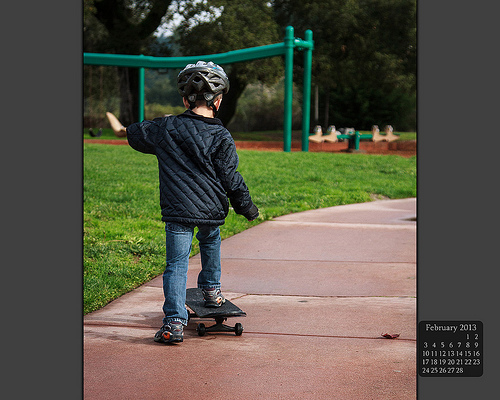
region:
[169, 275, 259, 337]
boy on a skateboard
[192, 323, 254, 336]
wheels on a skateboard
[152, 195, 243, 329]
boy is wearing jeans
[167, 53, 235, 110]
boy is wearing a helmet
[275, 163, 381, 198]
grass by the sidewalk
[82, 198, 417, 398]
sidewalk by the grass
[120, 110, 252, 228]
boy is wearing a black jacket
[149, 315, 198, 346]
boy is wearing a red and black shoe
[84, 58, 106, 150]
swing by the grass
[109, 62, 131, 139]
swing by the grass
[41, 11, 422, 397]
This is in a park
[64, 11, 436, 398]
This is during the daytime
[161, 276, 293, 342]
This kid is on a skateboard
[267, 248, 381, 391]
This ground is pavement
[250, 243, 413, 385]
This pavement is red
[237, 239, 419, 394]
The path is partially wet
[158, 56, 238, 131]
The kids has on a helmet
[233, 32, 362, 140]
These poles are made of metal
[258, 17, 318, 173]
These poles are green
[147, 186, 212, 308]
The kid has jeans on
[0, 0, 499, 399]
Page from a custom-made calendar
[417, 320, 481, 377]
Calendar listing the days of February 2013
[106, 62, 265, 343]
Little boy skateboarding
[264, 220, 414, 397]
Wet concrete sidewalk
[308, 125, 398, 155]
Teeter totters at a park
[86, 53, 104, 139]
Swing with black rubber seat at a park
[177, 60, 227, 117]
Boy wearing safety helmet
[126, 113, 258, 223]
Boy wearing black coat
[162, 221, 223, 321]
Boy wearing blue jeans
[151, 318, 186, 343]
Young boys tennis shoe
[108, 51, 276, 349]
little boy on a skateboard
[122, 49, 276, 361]
kid skateboarding on the sidewalk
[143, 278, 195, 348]
one foot on the sidewalk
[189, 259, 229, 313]
one foot on the skateboard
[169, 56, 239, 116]
helmet on the head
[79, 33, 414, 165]
playground in the grass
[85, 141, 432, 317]
grass on the ground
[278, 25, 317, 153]
two green poles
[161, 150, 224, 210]
wrinkles in the jacket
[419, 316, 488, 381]
calendar in the corner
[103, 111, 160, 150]
hand of rider outstreched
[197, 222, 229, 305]
leg of rider by side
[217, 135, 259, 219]
hand of rider by side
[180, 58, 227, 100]
black helmet of rider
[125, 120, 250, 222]
jacket of rider is black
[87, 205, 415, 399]
pavement is damp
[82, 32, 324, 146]
green pole in play ground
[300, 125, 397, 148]
green see saw with brown seats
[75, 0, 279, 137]
tree behind swing set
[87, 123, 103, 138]
swing hanging on chain